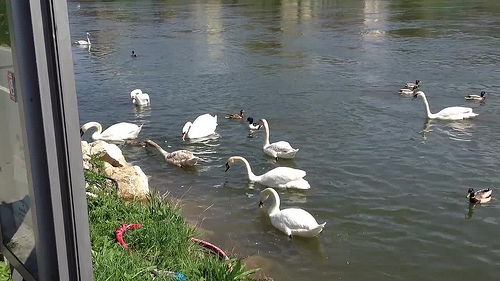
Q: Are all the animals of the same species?
A: No, there are both swans and birds.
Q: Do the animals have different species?
A: Yes, they are swans and birds.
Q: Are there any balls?
A: No, there are no balls.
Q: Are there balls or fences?
A: No, there are no balls or fences.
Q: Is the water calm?
A: Yes, the water is calm.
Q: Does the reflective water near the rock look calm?
A: Yes, the water is calm.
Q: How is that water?
A: The water is calm.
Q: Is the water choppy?
A: No, the water is calm.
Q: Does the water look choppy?
A: No, the water is calm.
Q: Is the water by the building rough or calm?
A: The water is calm.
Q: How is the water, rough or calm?
A: The water is calm.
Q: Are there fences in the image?
A: No, there are no fences.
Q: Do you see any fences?
A: No, there are no fences.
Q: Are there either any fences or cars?
A: No, there are no fences or cars.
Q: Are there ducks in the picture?
A: Yes, there is a duck.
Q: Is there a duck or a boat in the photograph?
A: Yes, there is a duck.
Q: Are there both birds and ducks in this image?
A: Yes, there are both a duck and birds.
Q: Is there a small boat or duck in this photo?
A: Yes, there is a small duck.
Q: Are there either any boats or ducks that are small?
A: Yes, the duck is small.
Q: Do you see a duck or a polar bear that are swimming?
A: Yes, the duck is swimming.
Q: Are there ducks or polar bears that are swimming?
A: Yes, the duck is swimming.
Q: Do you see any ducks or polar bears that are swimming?
A: Yes, the duck is swimming.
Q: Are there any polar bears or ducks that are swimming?
A: Yes, the duck is swimming.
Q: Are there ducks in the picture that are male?
A: Yes, there is a male duck.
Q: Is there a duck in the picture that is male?
A: Yes, there is a duck that is male.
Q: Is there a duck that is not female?
A: Yes, there is a male duck.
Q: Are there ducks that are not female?
A: Yes, there is a male duck.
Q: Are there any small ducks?
A: Yes, there is a small duck.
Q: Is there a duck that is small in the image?
A: Yes, there is a small duck.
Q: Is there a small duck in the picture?
A: Yes, there is a small duck.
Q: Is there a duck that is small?
A: Yes, there is a duck that is small.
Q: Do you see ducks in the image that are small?
A: Yes, there is a duck that is small.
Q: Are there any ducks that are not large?
A: Yes, there is a small duck.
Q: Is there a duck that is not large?
A: Yes, there is a small duck.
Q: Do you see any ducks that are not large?
A: Yes, there is a small duck.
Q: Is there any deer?
A: No, there is no deer.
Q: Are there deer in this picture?
A: No, there are no deer.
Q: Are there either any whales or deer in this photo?
A: No, there are no deer or whales.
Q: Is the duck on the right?
A: Yes, the duck is on the right of the image.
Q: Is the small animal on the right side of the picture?
A: Yes, the duck is on the right of the image.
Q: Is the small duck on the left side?
A: No, the duck is on the right of the image.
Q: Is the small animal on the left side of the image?
A: No, the duck is on the right of the image.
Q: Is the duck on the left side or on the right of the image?
A: The duck is on the right of the image.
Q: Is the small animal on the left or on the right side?
A: The duck is on the right of the image.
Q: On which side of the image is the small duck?
A: The duck is on the right of the image.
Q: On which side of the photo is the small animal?
A: The duck is on the right of the image.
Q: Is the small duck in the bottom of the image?
A: Yes, the duck is in the bottom of the image.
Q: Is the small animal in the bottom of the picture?
A: Yes, the duck is in the bottom of the image.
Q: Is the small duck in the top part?
A: No, the duck is in the bottom of the image.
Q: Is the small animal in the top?
A: No, the duck is in the bottom of the image.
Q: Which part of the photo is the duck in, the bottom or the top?
A: The duck is in the bottom of the image.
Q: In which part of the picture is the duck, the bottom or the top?
A: The duck is in the bottom of the image.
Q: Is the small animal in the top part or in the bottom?
A: The duck is in the bottom of the image.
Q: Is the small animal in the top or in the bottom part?
A: The duck is in the bottom of the image.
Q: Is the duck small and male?
A: Yes, the duck is small and male.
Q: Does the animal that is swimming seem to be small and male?
A: Yes, the duck is small and male.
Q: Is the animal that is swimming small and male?
A: Yes, the duck is small and male.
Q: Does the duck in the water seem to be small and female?
A: No, the duck is small but male.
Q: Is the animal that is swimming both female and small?
A: No, the duck is small but male.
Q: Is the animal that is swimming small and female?
A: No, the duck is small but male.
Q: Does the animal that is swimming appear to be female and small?
A: No, the duck is small but male.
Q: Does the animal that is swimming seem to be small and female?
A: No, the duck is small but male.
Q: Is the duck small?
A: Yes, the duck is small.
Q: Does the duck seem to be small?
A: Yes, the duck is small.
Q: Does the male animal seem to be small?
A: Yes, the duck is small.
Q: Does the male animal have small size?
A: Yes, the duck is small.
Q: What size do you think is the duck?
A: The duck is small.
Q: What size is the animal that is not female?
A: The duck is small.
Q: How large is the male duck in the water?
A: The duck is small.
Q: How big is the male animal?
A: The duck is small.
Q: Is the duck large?
A: No, the duck is small.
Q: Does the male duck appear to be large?
A: No, the duck is small.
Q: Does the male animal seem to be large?
A: No, the duck is small.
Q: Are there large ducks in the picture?
A: No, there is a duck but he is small.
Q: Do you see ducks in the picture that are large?
A: No, there is a duck but he is small.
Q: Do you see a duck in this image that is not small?
A: No, there is a duck but he is small.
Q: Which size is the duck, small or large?
A: The duck is small.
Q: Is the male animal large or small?
A: The duck is small.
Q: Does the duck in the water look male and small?
A: Yes, the duck is male and small.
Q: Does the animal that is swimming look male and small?
A: Yes, the duck is male and small.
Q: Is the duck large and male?
A: No, the duck is male but small.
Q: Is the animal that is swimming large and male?
A: No, the duck is male but small.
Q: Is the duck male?
A: Yes, the duck is male.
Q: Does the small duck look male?
A: Yes, the duck is male.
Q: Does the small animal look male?
A: Yes, the duck is male.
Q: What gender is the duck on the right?
A: The duck is male.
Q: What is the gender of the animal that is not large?
A: The duck is male.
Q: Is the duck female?
A: No, the duck is male.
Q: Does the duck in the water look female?
A: No, the duck is male.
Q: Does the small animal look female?
A: No, the duck is male.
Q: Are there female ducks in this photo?
A: No, there is a duck but he is male.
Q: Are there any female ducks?
A: No, there is a duck but he is male.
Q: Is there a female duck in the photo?
A: No, there is a duck but he is male.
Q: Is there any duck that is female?
A: No, there is a duck but he is male.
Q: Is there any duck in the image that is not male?
A: No, there is a duck but he is male.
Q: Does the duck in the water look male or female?
A: The duck is male.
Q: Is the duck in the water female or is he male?
A: The duck is male.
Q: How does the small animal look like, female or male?
A: The duck is male.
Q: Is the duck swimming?
A: Yes, the duck is swimming.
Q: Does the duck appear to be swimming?
A: Yes, the duck is swimming.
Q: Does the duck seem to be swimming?
A: Yes, the duck is swimming.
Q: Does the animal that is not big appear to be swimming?
A: Yes, the duck is swimming.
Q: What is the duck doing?
A: The duck is swimming.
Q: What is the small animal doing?
A: The duck is swimming.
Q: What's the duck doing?
A: The duck is swimming.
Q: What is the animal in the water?
A: The animal is a duck.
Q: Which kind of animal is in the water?
A: The animal is a duck.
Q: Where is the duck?
A: The duck is in the water.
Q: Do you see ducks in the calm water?
A: Yes, there is a duck in the water.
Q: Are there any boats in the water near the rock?
A: No, there is a duck in the water.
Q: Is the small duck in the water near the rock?
A: Yes, the duck is in the water.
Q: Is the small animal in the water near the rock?
A: Yes, the duck is in the water.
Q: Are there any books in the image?
A: No, there are no books.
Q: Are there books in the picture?
A: No, there are no books.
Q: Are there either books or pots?
A: No, there are no books or pots.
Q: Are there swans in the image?
A: Yes, there is a swan.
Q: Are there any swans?
A: Yes, there is a swan.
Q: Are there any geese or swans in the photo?
A: Yes, there is a swan.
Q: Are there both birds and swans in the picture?
A: Yes, there are both a swan and a bird.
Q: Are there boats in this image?
A: No, there are no boats.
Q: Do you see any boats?
A: No, there are no boats.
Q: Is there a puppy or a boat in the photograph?
A: No, there are no boats or puppies.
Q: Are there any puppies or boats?
A: No, there are no boats or puppies.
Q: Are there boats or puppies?
A: No, there are no boats or puppies.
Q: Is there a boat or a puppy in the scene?
A: No, there are no boats or puppies.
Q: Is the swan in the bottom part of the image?
A: Yes, the swan is in the bottom of the image.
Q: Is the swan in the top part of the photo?
A: No, the swan is in the bottom of the image.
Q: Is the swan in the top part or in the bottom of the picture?
A: The swan is in the bottom of the image.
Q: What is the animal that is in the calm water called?
A: The animal is a swan.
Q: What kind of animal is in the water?
A: The animal is a swan.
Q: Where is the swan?
A: The swan is in the water.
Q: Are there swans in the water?
A: Yes, there is a swan in the water.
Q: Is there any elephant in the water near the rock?
A: No, there is a swan in the water.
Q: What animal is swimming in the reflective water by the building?
A: The swan is swimming in the water.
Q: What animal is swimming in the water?
A: The swan is swimming in the water.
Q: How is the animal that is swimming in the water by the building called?
A: The animal is a swan.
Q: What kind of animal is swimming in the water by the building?
A: The animal is a swan.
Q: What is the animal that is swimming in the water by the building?
A: The animal is a swan.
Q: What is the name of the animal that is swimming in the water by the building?
A: The animal is a swan.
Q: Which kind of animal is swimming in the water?
A: The animal is a swan.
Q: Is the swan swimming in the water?
A: Yes, the swan is swimming in the water.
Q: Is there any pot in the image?
A: No, there are no pots.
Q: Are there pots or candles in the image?
A: No, there are no pots or candles.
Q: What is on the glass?
A: The sticker is on the glass.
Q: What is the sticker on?
A: The sticker is on the glass.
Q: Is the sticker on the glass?
A: Yes, the sticker is on the glass.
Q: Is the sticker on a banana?
A: No, the sticker is on the glass.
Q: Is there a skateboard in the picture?
A: No, there are no skateboards.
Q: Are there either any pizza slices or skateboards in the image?
A: No, there are no skateboards or pizza slices.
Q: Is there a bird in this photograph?
A: Yes, there is a bird.